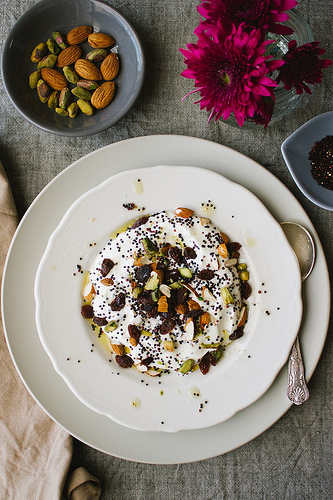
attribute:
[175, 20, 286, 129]
flower — red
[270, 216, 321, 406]
spoon — silver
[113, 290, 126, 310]
raisin — brown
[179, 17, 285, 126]
flowers —  pink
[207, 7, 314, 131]
jar —  mason's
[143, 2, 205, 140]
creases — table cloth's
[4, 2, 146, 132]
gray bowl. —  gray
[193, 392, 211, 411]
seeds — black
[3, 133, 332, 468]
plate — white, round,  white, small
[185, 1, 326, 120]
flowers — red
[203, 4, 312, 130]
vase — green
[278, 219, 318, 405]
spoon — silver, small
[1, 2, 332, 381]
tablecloth — gray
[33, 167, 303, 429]
plate — round, white, smaller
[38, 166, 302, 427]
bowl — white, round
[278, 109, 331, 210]
dish — silver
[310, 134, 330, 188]
poppy seeds — black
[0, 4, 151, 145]
bowl — grey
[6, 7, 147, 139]
bowl — grey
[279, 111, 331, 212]
bowl —  gray